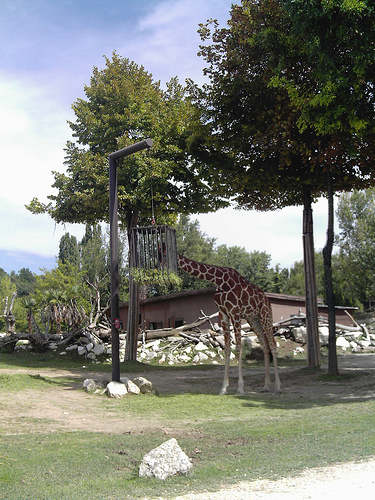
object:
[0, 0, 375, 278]
sky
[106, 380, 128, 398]
rocks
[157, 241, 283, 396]
giraffe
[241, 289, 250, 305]
spots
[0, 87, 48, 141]
clouds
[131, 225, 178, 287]
feeder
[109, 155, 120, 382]
pole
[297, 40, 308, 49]
leaves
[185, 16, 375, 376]
trees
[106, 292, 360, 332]
building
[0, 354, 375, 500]
ground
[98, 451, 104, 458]
grass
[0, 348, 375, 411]
shadow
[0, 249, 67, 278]
hill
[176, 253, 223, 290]
neck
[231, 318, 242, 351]
legs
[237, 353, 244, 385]
lower half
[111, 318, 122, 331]
item